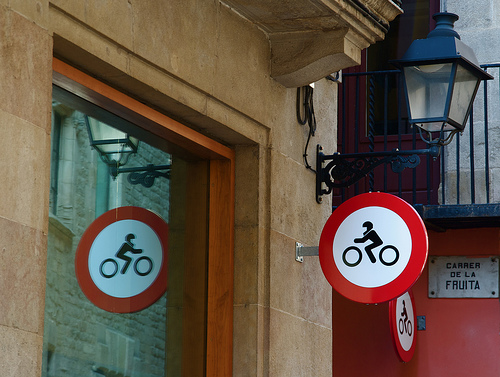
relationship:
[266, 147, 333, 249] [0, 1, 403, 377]
block in building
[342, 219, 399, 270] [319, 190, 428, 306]
biker on sign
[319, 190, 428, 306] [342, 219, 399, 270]
sign with a biker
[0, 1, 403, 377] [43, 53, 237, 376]
building has a window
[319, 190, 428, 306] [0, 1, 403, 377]
sign on building